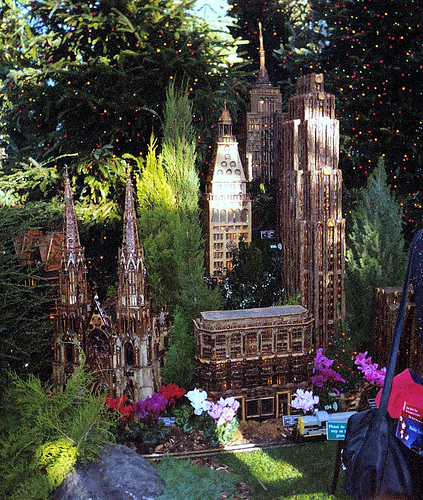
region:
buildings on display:
[30, 11, 417, 411]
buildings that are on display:
[18, 13, 415, 385]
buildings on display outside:
[25, 3, 418, 372]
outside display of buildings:
[16, 18, 422, 460]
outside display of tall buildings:
[13, 19, 419, 438]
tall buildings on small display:
[52, 19, 392, 417]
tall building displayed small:
[24, 25, 374, 421]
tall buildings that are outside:
[6, 15, 408, 402]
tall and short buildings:
[22, 18, 420, 461]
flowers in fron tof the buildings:
[83, 364, 297, 499]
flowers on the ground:
[105, 380, 239, 451]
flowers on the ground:
[254, 327, 410, 444]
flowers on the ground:
[84, 371, 207, 425]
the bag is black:
[335, 406, 399, 481]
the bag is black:
[330, 382, 419, 498]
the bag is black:
[301, 385, 393, 487]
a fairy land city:
[30, 27, 393, 480]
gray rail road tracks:
[161, 440, 295, 467]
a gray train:
[270, 405, 325, 440]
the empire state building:
[244, 20, 278, 176]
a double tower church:
[56, 164, 137, 401]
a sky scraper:
[282, 73, 349, 340]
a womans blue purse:
[328, 232, 419, 490]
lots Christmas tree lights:
[332, 3, 413, 102]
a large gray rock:
[48, 446, 182, 495]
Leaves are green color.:
[59, 31, 148, 121]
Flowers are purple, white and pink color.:
[115, 377, 364, 418]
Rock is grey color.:
[55, 438, 152, 491]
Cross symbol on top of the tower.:
[46, 154, 87, 207]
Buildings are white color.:
[40, 169, 359, 363]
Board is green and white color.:
[318, 415, 351, 448]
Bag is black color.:
[328, 405, 422, 488]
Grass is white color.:
[240, 458, 320, 496]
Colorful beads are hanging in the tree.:
[327, 53, 418, 161]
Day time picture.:
[19, 183, 365, 489]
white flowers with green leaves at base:
[181, 386, 213, 421]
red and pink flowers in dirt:
[102, 382, 186, 435]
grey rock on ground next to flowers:
[32, 431, 169, 495]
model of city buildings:
[3, 15, 355, 433]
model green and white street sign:
[316, 415, 356, 447]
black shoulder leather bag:
[337, 220, 420, 496]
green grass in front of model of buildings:
[170, 444, 346, 493]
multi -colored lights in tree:
[233, 1, 419, 225]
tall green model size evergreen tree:
[346, 147, 405, 352]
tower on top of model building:
[215, 98, 235, 142]